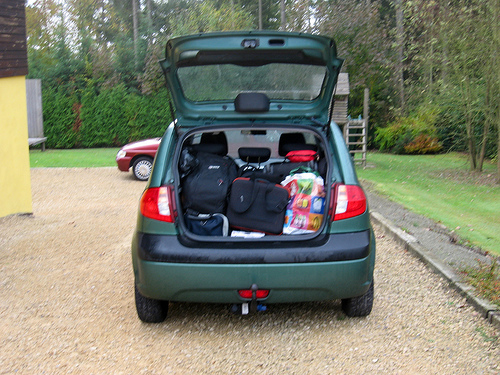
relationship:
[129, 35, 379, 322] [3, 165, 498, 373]
car on driveway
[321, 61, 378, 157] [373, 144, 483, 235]
playhouse on lawn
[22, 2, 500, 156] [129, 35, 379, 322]
wooded area behind car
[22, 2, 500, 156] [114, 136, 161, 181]
wooded area behind car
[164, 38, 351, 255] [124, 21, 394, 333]
trunk on car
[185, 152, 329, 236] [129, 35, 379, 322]
luggage piled in car